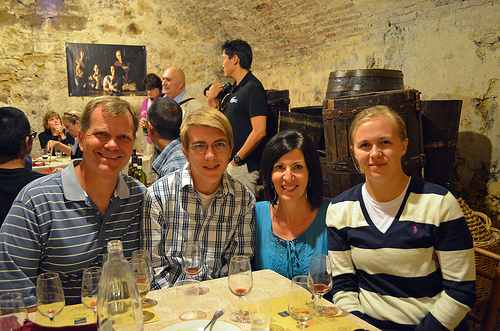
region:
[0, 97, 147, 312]
a man in a blue and white striped shirt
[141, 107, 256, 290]
boy in a blue and white plaid shirt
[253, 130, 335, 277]
woman in a turquoise blue sweater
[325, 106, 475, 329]
girl in a navy blue and white striped shirt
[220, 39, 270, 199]
man wearing a black shirt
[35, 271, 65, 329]
a wine glass on the table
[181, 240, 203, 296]
a wine glass on the table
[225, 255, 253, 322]
a wine glass on the table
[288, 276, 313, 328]
a wine glass on the table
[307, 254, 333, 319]
a wine glass on the table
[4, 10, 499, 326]
a restaurant is full of customers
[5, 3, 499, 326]
the restaurant is in a rock cave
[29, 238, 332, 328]
wine glasses are on the table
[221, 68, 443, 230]
kegs are against the wall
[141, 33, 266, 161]
a guitarist and a singer is in the room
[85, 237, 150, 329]
an empty bottle is on the table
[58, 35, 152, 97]
a poster is on the wall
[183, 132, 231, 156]
the boy is wearing eyeglasses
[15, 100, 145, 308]
the man is wearing a polo shirt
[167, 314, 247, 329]
an empty plate is on the table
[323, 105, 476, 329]
Woman wearing striped shirt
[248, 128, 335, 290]
Woman wearing blue shirt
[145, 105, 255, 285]
Man has blonde hair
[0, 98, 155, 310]
Man has striped shirt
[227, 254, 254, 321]
Empty wine glass on table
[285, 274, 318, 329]
Empty wine glass on table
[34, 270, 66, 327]
Empty wine glass on table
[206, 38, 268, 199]
Man in black shirt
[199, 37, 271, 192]
Man is holding camera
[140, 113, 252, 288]
Man is wearing eye glasses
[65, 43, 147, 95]
picture hanging on the wall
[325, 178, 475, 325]
stripe V neck sweater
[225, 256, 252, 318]
empty wine glass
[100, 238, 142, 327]
top of a clear bottle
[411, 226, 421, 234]
pink logo on the sweater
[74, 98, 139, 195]
the man is smiling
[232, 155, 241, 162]
a black wrist watch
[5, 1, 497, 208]
old aged brick wall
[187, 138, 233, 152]
eye glasses on the boy's face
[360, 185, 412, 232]
plain white tee shirt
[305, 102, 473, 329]
Woman wearing a striped sweater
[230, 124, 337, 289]
Woman wearing a blue shirt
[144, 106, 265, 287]
Man wearing a plaid shirt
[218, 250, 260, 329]
Wine glass on the table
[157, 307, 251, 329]
Plate on the table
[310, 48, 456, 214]
Barrel behind the woman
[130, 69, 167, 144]
Woman wearing a purple sweater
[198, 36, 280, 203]
Man wearing a black shirt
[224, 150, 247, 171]
Watch on man's wrist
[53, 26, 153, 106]
Picture hanging on the wall